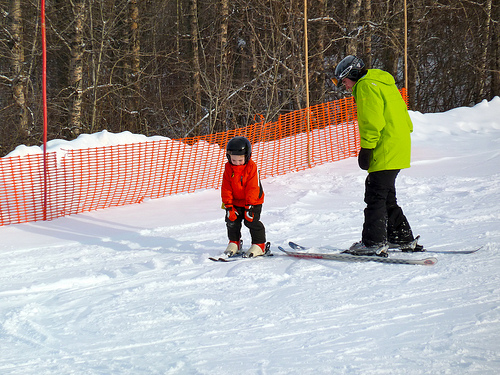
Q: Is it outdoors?
A: Yes, it is outdoors.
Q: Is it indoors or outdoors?
A: It is outdoors.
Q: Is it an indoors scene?
A: No, it is outdoors.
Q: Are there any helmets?
A: Yes, there is a helmet.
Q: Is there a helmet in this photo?
A: Yes, there is a helmet.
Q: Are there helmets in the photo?
A: Yes, there is a helmet.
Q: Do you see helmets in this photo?
A: Yes, there is a helmet.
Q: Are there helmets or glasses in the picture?
A: Yes, there is a helmet.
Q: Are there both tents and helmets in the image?
A: No, there is a helmet but no tents.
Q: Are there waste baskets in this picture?
A: No, there are no waste baskets.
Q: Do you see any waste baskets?
A: No, there are no waste baskets.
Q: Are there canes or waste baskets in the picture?
A: No, there are no waste baskets or canes.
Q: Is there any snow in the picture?
A: Yes, there is snow.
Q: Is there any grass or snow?
A: Yes, there is snow.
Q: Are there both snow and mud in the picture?
A: No, there is snow but no mud.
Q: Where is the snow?
A: The snow is on the hill.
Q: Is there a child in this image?
A: Yes, there is a child.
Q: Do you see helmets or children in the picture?
A: Yes, there is a child.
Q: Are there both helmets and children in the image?
A: Yes, there are both a child and a helmet.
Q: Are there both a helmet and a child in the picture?
A: Yes, there are both a child and a helmet.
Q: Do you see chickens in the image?
A: No, there are no chickens.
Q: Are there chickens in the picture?
A: No, there are no chickens.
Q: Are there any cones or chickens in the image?
A: No, there are no chickens or cones.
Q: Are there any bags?
A: No, there are no bags.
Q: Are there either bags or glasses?
A: No, there are no bags or glasses.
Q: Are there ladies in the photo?
A: No, there are no ladies.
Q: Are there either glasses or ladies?
A: No, there are no ladies or glasses.